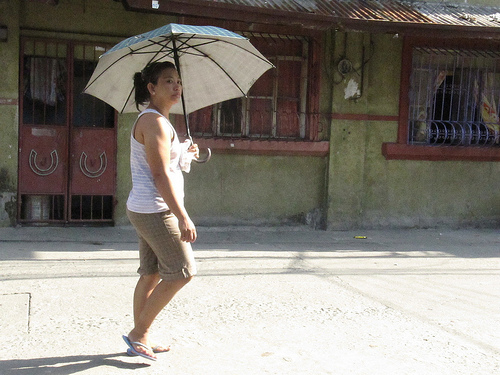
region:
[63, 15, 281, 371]
woman walking with umbrella down a sidewalk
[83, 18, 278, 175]
open umbrellla in woman's hand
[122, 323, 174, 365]
pair of pastel flip flops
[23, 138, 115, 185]
two horseshoe shapes on metal rail doorways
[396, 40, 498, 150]
window with thin metal boards covering it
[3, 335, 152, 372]
shadow of woman walking on sidewalk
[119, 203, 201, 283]
pair of tan pants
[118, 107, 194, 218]
white striped tank top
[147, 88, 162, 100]
one earring in person's ear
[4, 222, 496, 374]
long stretch of paved tan sidewalk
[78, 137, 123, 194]
white horse shoe on right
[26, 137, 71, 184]
white horse shoe on left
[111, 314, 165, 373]
light blue sandals on woman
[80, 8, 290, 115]
blue and white striped umbrella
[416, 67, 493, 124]
silver metal bars on window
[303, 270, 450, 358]
white ragged concrete road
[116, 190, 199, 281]
beige checked capri shorts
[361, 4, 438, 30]
rusted metal roof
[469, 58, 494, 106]
yellow faded curtains in window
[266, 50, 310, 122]
red faded curtain in window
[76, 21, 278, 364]
A person holding an umbrella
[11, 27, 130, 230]
A red door behind the person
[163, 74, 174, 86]
The eye of the person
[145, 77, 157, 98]
The ear of the person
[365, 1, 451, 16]
Part of the building's roof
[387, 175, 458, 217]
Part of the building's wall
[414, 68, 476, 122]
Part of the building's window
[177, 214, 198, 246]
The right hand of the person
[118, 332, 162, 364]
The right foot of the person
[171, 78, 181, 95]
The nose of the person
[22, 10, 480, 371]
The woman is in the city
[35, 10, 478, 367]
The woman is casually walking around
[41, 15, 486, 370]
The woman is holding an umbrella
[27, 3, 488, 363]
The woman is out in the sunshine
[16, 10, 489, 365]
A woman is going to see a friend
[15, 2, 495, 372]
A woman is walking on pavement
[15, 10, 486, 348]
The woman is in an Asian country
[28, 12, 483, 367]
The woman is enjoying her day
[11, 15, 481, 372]
The woman is going grocery shopping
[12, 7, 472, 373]
The woman is looking at something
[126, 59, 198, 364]
woman holding white umbrella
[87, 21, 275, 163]
blue and white umbrella with black handle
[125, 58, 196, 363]
woman wearing white shirt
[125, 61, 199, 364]
woman wearing plaid shorts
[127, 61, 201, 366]
woman underneath umbrella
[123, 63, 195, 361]
woman walking in front of building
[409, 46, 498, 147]
window covered with metal bars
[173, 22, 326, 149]
window covered with metal bars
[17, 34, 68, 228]
door made of metal bars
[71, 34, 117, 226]
door made of metal bars